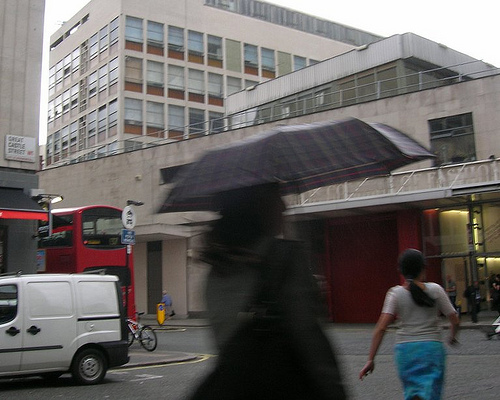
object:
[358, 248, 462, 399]
girl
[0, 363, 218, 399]
street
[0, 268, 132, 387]
van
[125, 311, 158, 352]
bike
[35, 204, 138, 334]
bus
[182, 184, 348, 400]
lady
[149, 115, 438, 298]
umbrella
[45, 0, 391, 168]
building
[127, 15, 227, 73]
window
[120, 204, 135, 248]
sign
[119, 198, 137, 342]
pole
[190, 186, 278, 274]
hair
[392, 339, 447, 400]
skirt